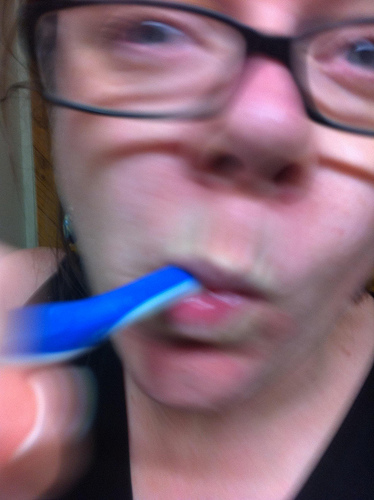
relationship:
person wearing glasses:
[1, 1, 373, 500] [18, 0, 373, 138]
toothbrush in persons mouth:
[1, 265, 203, 368] [149, 255, 276, 327]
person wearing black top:
[1, 1, 373, 500] [4, 251, 373, 499]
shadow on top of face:
[64, 79, 373, 187] [52, 0, 373, 407]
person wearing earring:
[1, 1, 373, 500] [61, 216, 79, 254]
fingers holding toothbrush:
[1, 364, 95, 500] [1, 265, 203, 368]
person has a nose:
[1, 1, 373, 500] [192, 41, 315, 197]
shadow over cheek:
[64, 79, 373, 187] [55, 118, 174, 231]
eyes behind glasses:
[113, 17, 374, 73] [18, 0, 373, 138]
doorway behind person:
[17, 2, 78, 251] [1, 1, 373, 500]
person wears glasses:
[1, 1, 373, 500] [18, 0, 373, 138]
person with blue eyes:
[1, 1, 373, 500] [113, 17, 374, 73]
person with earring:
[1, 1, 373, 500] [61, 216, 79, 254]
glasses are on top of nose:
[18, 0, 373, 138] [192, 41, 315, 197]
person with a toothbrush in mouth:
[1, 1, 373, 500] [149, 255, 276, 327]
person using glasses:
[1, 1, 373, 500] [18, 0, 373, 138]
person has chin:
[1, 1, 373, 500] [112, 329, 292, 408]